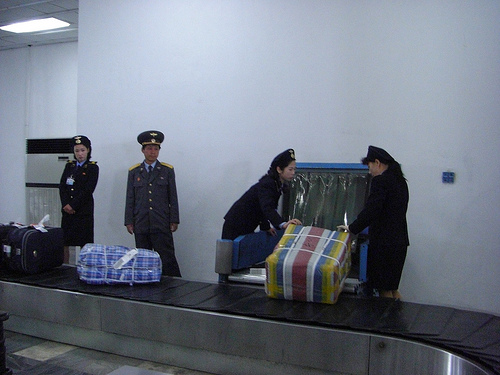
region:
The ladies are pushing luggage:
[260, 193, 454, 348]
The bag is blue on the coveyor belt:
[70, 233, 195, 292]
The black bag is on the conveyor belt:
[5, 214, 126, 320]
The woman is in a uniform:
[55, 122, 141, 241]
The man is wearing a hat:
[115, 125, 159, 170]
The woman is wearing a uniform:
[164, 129, 284, 233]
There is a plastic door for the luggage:
[283, 155, 363, 223]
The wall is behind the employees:
[168, 90, 273, 183]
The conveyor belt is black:
[65, 280, 306, 371]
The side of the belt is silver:
[48, 289, 249, 353]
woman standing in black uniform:
[60, 136, 100, 248]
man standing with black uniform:
[125, 130, 180, 275]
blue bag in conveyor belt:
[77, 242, 162, 282]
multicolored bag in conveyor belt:
[266, 222, 352, 302]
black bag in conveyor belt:
[0, 222, 59, 272]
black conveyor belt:
[0, 260, 498, 372]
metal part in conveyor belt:
[1, 279, 486, 374]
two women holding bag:
[222, 142, 410, 299]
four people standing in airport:
[56, 131, 411, 298]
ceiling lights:
[0, 12, 72, 34]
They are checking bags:
[53, 121, 405, 330]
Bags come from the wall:
[267, 152, 384, 309]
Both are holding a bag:
[207, 130, 429, 286]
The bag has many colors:
[267, 230, 346, 299]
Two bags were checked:
[0, 210, 180, 307]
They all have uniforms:
[35, 143, 453, 301]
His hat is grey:
[124, 134, 165, 146]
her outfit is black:
[369, 163, 397, 278]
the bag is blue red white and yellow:
[230, 220, 372, 309]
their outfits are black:
[199, 149, 432, 306]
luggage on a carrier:
[76, 236, 176, 295]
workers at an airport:
[56, 127, 213, 294]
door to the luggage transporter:
[302, 164, 359, 230]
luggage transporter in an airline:
[352, 289, 497, 370]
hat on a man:
[136, 127, 166, 152]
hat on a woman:
[67, 129, 97, 152]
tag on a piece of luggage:
[111, 245, 143, 272]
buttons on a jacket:
[143, 174, 160, 224]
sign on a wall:
[440, 164, 462, 194]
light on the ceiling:
[2, 8, 72, 51]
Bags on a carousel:
[1, 214, 497, 373]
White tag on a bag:
[115, 244, 141, 271]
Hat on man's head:
[137, 124, 166, 164]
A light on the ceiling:
[1, 13, 70, 39]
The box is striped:
[261, 219, 356, 310]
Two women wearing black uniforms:
[216, 140, 415, 299]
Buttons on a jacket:
[141, 176, 159, 216]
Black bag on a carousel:
[1, 214, 67, 281]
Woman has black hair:
[63, 131, 93, 165]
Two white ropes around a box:
[276, 229, 348, 269]